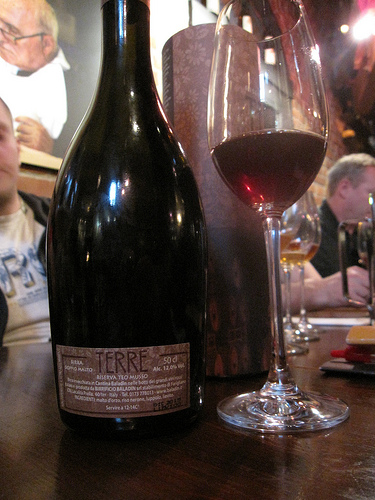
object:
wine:
[207, 130, 329, 213]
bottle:
[37, 0, 215, 428]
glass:
[205, 0, 356, 438]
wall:
[1, 2, 359, 232]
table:
[3, 302, 375, 499]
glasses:
[273, 188, 310, 358]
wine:
[279, 251, 307, 265]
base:
[216, 381, 351, 442]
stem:
[261, 216, 298, 392]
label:
[50, 340, 193, 421]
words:
[98, 380, 120, 400]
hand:
[321, 262, 372, 311]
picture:
[1, 1, 103, 159]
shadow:
[59, 409, 301, 498]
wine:
[280, 233, 294, 252]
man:
[309, 150, 375, 283]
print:
[178, 68, 201, 101]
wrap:
[158, 23, 276, 379]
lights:
[352, 13, 375, 43]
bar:
[0, 0, 375, 499]